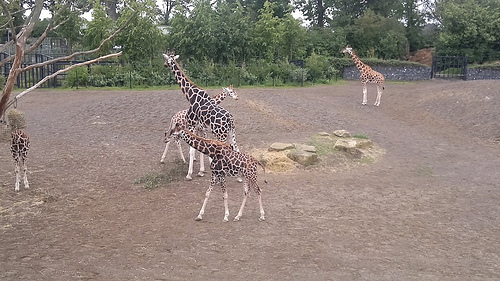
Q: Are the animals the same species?
A: Yes, all the animals are giraffes.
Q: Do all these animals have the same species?
A: Yes, all the animals are giraffes.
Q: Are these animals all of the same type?
A: Yes, all the animals are giraffes.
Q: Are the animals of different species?
A: No, all the animals are giraffes.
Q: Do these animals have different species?
A: No, all the animals are giraffes.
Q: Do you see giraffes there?
A: Yes, there are giraffes.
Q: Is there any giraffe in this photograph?
A: Yes, there are giraffes.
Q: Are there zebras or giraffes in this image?
A: Yes, there are giraffes.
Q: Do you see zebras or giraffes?
A: Yes, there are giraffes.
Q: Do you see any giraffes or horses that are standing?
A: Yes, the giraffes are standing.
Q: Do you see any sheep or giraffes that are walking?
A: Yes, the giraffes are walking.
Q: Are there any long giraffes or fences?
A: Yes, there are long giraffes.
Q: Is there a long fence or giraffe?
A: Yes, there are long giraffes.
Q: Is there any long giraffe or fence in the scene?
A: Yes, there are long giraffes.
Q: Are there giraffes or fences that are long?
A: Yes, the giraffes are long.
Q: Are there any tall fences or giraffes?
A: Yes, there are tall giraffes.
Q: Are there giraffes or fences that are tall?
A: Yes, the giraffes are tall.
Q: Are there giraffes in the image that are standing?
A: Yes, there are giraffes that are standing.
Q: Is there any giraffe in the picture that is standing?
A: Yes, there are giraffes that are standing.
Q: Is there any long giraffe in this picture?
A: Yes, there are long giraffes.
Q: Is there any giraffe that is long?
A: Yes, there are giraffes that are long.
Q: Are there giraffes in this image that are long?
A: Yes, there are giraffes that are long.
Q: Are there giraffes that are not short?
A: Yes, there are long giraffes.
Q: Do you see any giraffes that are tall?
A: Yes, there are tall giraffes.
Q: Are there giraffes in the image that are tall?
A: Yes, there are giraffes that are tall.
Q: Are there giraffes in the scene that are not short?
A: Yes, there are tall giraffes.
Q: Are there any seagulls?
A: No, there are no seagulls.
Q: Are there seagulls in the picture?
A: No, there are no seagulls.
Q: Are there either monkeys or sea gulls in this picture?
A: No, there are no sea gulls or monkeys.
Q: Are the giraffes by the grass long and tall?
A: Yes, the giraffes are long and tall.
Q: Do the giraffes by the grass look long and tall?
A: Yes, the giraffes are long and tall.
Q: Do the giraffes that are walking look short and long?
A: No, the giraffes are long but tall.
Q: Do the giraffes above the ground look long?
A: Yes, the giraffes are long.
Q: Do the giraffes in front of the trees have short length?
A: No, the giraffes are long.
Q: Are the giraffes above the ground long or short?
A: The giraffes are long.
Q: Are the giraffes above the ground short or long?
A: The giraffes are long.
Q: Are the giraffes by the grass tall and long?
A: Yes, the giraffes are tall and long.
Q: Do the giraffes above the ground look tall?
A: Yes, the giraffes are tall.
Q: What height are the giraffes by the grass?
A: The giraffes are tall.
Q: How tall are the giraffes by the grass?
A: The giraffes are tall.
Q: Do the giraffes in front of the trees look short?
A: No, the giraffes are tall.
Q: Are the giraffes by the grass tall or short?
A: The giraffes are tall.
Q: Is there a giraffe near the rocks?
A: Yes, there are giraffes near the rocks.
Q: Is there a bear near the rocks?
A: No, there are giraffes near the rocks.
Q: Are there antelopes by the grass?
A: No, there are giraffes by the grass.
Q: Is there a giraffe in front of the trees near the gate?
A: Yes, there are giraffes in front of the trees.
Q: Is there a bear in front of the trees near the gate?
A: No, there are giraffes in front of the trees.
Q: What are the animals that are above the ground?
A: The animals are giraffes.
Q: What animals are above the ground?
A: The animals are giraffes.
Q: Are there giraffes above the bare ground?
A: Yes, there are giraffes above the ground.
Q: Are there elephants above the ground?
A: No, there are giraffes above the ground.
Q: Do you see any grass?
A: Yes, there is grass.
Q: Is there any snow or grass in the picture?
A: Yes, there is grass.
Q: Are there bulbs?
A: No, there are no bulbs.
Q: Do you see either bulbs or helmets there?
A: No, there are no bulbs or helmets.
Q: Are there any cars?
A: No, there are no cars.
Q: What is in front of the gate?
A: The tree is in front of the gate.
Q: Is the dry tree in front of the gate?
A: Yes, the tree is in front of the gate.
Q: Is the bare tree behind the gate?
A: No, the tree is in front of the gate.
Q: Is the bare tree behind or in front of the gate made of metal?
A: The tree is in front of the gate.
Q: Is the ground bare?
A: Yes, the ground is bare.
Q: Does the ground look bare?
A: Yes, the ground is bare.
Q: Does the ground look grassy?
A: No, the ground is bare.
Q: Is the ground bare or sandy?
A: The ground is bare.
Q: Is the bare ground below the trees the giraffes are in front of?
A: Yes, the ground is below the trees.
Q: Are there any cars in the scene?
A: No, there are no cars.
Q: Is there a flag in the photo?
A: No, there are no flags.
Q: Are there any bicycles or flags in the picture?
A: No, there are no flags or bicycles.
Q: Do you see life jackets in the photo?
A: No, there are no life jackets.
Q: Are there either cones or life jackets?
A: No, there are no life jackets or cones.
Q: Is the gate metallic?
A: Yes, the gate is metallic.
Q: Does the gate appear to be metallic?
A: Yes, the gate is metallic.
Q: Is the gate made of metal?
A: Yes, the gate is made of metal.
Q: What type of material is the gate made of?
A: The gate is made of metal.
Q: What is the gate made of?
A: The gate is made of metal.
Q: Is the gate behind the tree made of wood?
A: No, the gate is made of metal.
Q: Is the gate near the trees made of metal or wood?
A: The gate is made of metal.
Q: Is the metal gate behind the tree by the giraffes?
A: Yes, the gate is behind the tree.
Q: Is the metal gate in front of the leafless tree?
A: No, the gate is behind the tree.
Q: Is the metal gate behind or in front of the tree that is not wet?
A: The gate is behind the tree.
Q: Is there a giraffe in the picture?
A: Yes, there is a giraffe.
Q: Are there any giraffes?
A: Yes, there is a giraffe.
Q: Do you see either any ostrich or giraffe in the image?
A: Yes, there is a giraffe.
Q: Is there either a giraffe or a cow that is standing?
A: Yes, the giraffe is standing.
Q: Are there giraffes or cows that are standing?
A: Yes, the giraffe is standing.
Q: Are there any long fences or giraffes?
A: Yes, there is a long giraffe.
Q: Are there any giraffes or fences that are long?
A: Yes, the giraffe is long.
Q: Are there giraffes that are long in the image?
A: Yes, there is a long giraffe.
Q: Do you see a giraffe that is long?
A: Yes, there is a giraffe that is long.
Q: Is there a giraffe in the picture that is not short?
A: Yes, there is a long giraffe.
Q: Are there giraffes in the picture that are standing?
A: Yes, there is a giraffe that is standing.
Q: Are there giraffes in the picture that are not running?
A: Yes, there is a giraffe that is standing.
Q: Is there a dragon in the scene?
A: No, there are no dragons.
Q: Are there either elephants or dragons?
A: No, there are no dragons or elephants.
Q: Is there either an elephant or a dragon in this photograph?
A: No, there are no dragons or elephants.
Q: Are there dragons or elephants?
A: No, there are no dragons or elephants.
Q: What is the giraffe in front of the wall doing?
A: The giraffe is standing.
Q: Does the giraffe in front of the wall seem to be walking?
A: No, the giraffe is standing.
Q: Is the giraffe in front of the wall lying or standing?
A: The giraffe is standing.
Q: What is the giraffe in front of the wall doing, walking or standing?
A: The giraffe is standing.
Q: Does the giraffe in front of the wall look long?
A: Yes, the giraffe is long.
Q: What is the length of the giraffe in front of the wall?
A: The giraffe is long.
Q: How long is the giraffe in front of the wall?
A: The giraffe is long.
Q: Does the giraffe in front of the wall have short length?
A: No, the giraffe is long.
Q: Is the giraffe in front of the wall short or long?
A: The giraffe is long.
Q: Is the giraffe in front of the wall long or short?
A: The giraffe is long.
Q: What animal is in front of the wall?
A: The giraffe is in front of the wall.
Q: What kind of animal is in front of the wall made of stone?
A: The animal is a giraffe.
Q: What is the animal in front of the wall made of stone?
A: The animal is a giraffe.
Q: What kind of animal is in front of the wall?
A: The animal is a giraffe.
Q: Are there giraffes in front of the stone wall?
A: Yes, there is a giraffe in front of the wall.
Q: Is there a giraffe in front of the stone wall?
A: Yes, there is a giraffe in front of the wall.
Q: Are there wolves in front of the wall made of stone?
A: No, there is a giraffe in front of the wall.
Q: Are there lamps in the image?
A: No, there are no lamps.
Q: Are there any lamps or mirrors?
A: No, there are no lamps or mirrors.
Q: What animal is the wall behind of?
A: The wall is behind the giraffe.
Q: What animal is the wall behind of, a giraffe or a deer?
A: The wall is behind a giraffe.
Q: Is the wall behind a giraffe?
A: Yes, the wall is behind a giraffe.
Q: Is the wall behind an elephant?
A: No, the wall is behind a giraffe.